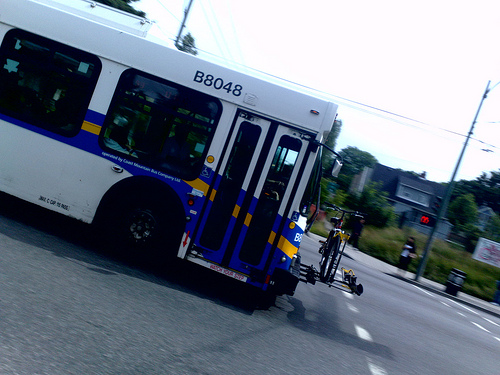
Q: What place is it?
A: It is a street.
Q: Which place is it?
A: It is a street.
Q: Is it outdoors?
A: Yes, it is outdoors.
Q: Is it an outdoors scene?
A: Yes, it is outdoors.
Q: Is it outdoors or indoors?
A: It is outdoors.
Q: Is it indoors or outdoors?
A: It is outdoors.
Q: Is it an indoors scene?
A: No, it is outdoors.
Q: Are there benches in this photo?
A: No, there are no benches.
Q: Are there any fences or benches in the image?
A: No, there are no benches or fences.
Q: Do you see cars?
A: No, there are no cars.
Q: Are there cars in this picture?
A: No, there are no cars.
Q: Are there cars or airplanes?
A: No, there are no cars or airplanes.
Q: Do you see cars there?
A: No, there are no cars.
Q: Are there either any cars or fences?
A: No, there are no cars or fences.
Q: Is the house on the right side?
A: Yes, the house is on the right of the image.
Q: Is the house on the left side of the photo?
A: No, the house is on the right of the image.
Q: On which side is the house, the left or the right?
A: The house is on the right of the image.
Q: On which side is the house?
A: The house is on the right of the image.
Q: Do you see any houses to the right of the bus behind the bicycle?
A: Yes, there is a house to the right of the bus.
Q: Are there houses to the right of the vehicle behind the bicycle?
A: Yes, there is a house to the right of the bus.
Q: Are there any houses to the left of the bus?
A: No, the house is to the right of the bus.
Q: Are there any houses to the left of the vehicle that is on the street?
A: No, the house is to the right of the bus.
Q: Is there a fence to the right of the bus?
A: No, there is a house to the right of the bus.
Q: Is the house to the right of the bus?
A: Yes, the house is to the right of the bus.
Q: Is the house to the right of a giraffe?
A: No, the house is to the right of the bus.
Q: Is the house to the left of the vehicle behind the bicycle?
A: No, the house is to the right of the bus.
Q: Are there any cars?
A: No, there are no cars.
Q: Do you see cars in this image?
A: No, there are no cars.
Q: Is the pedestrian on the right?
A: Yes, the pedestrian is on the right of the image.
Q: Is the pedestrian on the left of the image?
A: No, the pedestrian is on the right of the image.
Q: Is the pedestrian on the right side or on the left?
A: The pedestrian is on the right of the image.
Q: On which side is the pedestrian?
A: The pedestrian is on the right of the image.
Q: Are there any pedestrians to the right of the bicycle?
A: Yes, there is a pedestrian to the right of the bicycle.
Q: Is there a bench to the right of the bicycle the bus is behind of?
A: No, there is a pedestrian to the right of the bicycle.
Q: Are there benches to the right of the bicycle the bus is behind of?
A: No, there is a pedestrian to the right of the bicycle.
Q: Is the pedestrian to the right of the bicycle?
A: Yes, the pedestrian is to the right of the bicycle.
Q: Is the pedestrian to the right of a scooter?
A: No, the pedestrian is to the right of the bicycle.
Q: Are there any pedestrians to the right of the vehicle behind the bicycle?
A: Yes, there is a pedestrian to the right of the bus.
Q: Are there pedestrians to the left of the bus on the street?
A: No, the pedestrian is to the right of the bus.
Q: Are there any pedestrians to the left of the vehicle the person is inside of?
A: No, the pedestrian is to the right of the bus.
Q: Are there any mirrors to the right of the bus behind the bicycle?
A: No, there is a pedestrian to the right of the bus.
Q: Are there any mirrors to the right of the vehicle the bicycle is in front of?
A: No, there is a pedestrian to the right of the bus.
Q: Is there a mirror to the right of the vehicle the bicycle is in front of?
A: No, there is a pedestrian to the right of the bus.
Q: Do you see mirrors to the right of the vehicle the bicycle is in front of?
A: No, there is a pedestrian to the right of the bus.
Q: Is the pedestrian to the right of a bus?
A: Yes, the pedestrian is to the right of a bus.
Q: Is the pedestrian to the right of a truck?
A: No, the pedestrian is to the right of a bus.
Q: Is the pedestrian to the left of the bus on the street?
A: No, the pedestrian is to the right of the bus.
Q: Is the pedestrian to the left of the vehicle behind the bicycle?
A: No, the pedestrian is to the right of the bus.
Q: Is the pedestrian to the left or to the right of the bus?
A: The pedestrian is to the right of the bus.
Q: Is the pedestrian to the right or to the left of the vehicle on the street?
A: The pedestrian is to the right of the bus.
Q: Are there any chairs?
A: No, there are no chairs.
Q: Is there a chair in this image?
A: No, there are no chairs.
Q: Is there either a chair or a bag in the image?
A: No, there are no chairs or bags.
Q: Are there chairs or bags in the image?
A: No, there are no chairs or bags.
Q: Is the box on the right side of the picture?
A: Yes, the box is on the right of the image.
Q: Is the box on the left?
A: No, the box is on the right of the image.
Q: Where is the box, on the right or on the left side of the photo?
A: The box is on the right of the image.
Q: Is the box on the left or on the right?
A: The box is on the right of the image.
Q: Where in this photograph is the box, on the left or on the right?
A: The box is on the right of the image.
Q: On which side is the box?
A: The box is on the right of the image.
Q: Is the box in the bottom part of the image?
A: Yes, the box is in the bottom of the image.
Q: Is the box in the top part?
A: No, the box is in the bottom of the image.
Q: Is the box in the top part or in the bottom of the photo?
A: The box is in the bottom of the image.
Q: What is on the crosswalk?
A: The box is on the crosswalk.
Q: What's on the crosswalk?
A: The box is on the crosswalk.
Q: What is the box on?
A: The box is on the crosswalk.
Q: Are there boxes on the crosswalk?
A: Yes, there is a box on the crosswalk.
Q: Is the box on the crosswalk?
A: Yes, the box is on the crosswalk.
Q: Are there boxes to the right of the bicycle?
A: Yes, there is a box to the right of the bicycle.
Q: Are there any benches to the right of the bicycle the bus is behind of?
A: No, there is a box to the right of the bicycle.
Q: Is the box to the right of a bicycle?
A: Yes, the box is to the right of a bicycle.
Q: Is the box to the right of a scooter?
A: No, the box is to the right of a bicycle.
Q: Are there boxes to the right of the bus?
A: Yes, there is a box to the right of the bus.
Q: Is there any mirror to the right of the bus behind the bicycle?
A: No, there is a box to the right of the bus.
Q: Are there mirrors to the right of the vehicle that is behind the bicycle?
A: No, there is a box to the right of the bus.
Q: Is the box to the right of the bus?
A: Yes, the box is to the right of the bus.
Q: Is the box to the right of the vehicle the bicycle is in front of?
A: Yes, the box is to the right of the bus.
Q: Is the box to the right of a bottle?
A: No, the box is to the right of the bus.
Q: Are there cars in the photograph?
A: No, there are no cars.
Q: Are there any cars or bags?
A: No, there are no cars or bags.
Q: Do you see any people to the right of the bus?
A: Yes, there is a person to the right of the bus.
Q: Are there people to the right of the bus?
A: Yes, there is a person to the right of the bus.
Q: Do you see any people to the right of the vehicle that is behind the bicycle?
A: Yes, there is a person to the right of the bus.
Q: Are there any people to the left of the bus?
A: No, the person is to the right of the bus.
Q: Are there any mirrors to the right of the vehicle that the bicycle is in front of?
A: No, there is a person to the right of the bus.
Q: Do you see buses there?
A: Yes, there is a bus.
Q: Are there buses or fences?
A: Yes, there is a bus.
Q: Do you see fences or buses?
A: Yes, there is a bus.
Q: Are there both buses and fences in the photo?
A: No, there is a bus but no fences.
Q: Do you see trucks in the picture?
A: No, there are no trucks.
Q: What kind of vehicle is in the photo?
A: The vehicle is a bus.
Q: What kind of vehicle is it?
A: The vehicle is a bus.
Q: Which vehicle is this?
A: This is a bus.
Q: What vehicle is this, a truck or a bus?
A: This is a bus.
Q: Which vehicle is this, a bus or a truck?
A: This is a bus.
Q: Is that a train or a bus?
A: That is a bus.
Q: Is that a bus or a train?
A: That is a bus.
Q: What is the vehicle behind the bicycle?
A: The vehicle is a bus.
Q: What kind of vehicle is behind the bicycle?
A: The vehicle is a bus.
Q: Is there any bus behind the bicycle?
A: Yes, there is a bus behind the bicycle.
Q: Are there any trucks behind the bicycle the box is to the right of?
A: No, there is a bus behind the bicycle.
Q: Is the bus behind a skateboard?
A: No, the bus is behind the bicycle.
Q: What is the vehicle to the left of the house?
A: The vehicle is a bus.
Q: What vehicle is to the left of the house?
A: The vehicle is a bus.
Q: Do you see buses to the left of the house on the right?
A: Yes, there is a bus to the left of the house.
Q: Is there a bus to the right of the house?
A: No, the bus is to the left of the house.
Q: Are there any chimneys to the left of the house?
A: No, there is a bus to the left of the house.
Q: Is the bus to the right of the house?
A: No, the bus is to the left of the house.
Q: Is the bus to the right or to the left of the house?
A: The bus is to the left of the house.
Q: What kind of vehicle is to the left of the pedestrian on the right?
A: The vehicle is a bus.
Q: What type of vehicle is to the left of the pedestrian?
A: The vehicle is a bus.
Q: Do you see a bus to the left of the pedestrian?
A: Yes, there is a bus to the left of the pedestrian.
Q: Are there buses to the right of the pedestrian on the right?
A: No, the bus is to the left of the pedestrian.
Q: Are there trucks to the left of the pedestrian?
A: No, there is a bus to the left of the pedestrian.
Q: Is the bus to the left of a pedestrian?
A: Yes, the bus is to the left of a pedestrian.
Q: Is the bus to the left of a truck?
A: No, the bus is to the left of a pedestrian.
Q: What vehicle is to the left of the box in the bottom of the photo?
A: The vehicle is a bus.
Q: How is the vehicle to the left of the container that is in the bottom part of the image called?
A: The vehicle is a bus.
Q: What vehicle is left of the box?
A: The vehicle is a bus.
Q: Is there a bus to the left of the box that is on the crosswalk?
A: Yes, there is a bus to the left of the box.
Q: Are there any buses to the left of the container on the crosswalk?
A: Yes, there is a bus to the left of the box.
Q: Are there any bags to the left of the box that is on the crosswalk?
A: No, there is a bus to the left of the box.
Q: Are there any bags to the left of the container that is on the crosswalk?
A: No, there is a bus to the left of the box.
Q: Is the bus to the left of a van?
A: No, the bus is to the left of the box.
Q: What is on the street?
A: The bus is on the street.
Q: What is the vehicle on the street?
A: The vehicle is a bus.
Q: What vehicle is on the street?
A: The vehicle is a bus.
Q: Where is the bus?
A: The bus is on the street.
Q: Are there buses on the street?
A: Yes, there is a bus on the street.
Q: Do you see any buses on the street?
A: Yes, there is a bus on the street.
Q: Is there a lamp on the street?
A: No, there is a bus on the street.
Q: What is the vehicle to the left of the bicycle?
A: The vehicle is a bus.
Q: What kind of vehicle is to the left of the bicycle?
A: The vehicle is a bus.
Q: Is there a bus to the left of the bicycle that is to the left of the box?
A: Yes, there is a bus to the left of the bicycle.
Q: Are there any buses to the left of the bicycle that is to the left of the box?
A: Yes, there is a bus to the left of the bicycle.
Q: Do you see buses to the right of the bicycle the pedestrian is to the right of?
A: No, the bus is to the left of the bicycle.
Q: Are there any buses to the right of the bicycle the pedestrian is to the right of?
A: No, the bus is to the left of the bicycle.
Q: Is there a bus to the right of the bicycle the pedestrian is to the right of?
A: No, the bus is to the left of the bicycle.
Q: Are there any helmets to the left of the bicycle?
A: No, there is a bus to the left of the bicycle.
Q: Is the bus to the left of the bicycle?
A: Yes, the bus is to the left of the bicycle.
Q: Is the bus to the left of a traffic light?
A: No, the bus is to the left of the bicycle.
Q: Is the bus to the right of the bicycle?
A: No, the bus is to the left of the bicycle.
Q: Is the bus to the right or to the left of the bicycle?
A: The bus is to the left of the bicycle.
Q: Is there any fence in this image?
A: No, there are no fences.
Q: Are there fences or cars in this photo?
A: No, there are no fences or cars.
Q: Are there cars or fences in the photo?
A: No, there are no fences or cars.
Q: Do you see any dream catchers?
A: No, there are no dream catchers.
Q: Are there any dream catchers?
A: No, there are no dream catchers.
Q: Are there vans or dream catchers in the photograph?
A: No, there are no dream catchers or vans.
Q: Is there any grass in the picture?
A: Yes, there is grass.